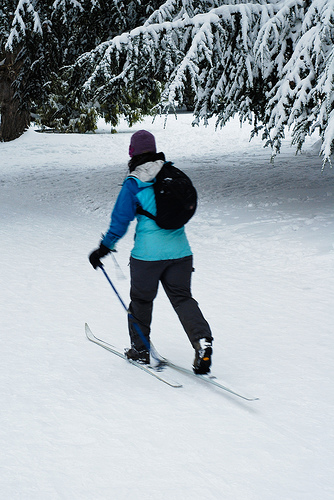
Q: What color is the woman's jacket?
A: Blue.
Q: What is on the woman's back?
A: Backpack.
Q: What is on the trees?
A: Snow.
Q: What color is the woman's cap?
A: Purple.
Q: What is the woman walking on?
A: Skis.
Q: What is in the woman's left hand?
A: Ski pole.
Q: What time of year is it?
A: Winter.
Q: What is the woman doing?
A: Skiing.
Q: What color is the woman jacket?
A: Blue.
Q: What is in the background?
A: Trees.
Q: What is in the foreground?
A: Snow.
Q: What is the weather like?
A: Cool and clear.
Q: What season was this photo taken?
A: Winter.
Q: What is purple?
A: Hat.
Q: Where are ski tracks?
A: On the snow.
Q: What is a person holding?
A: Ski poles.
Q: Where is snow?
A: On trees.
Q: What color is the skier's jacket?
A: Blue.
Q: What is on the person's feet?
A: Skis.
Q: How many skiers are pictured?
A: One.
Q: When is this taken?
A: Wintertime.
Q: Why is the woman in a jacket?
A: It's cold out.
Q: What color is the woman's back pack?
A: Black.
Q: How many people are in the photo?
A: One.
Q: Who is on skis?
A: The woman.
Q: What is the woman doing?
A: Cross country skiing.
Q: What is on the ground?
A: Snow.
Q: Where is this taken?
A: In a park.